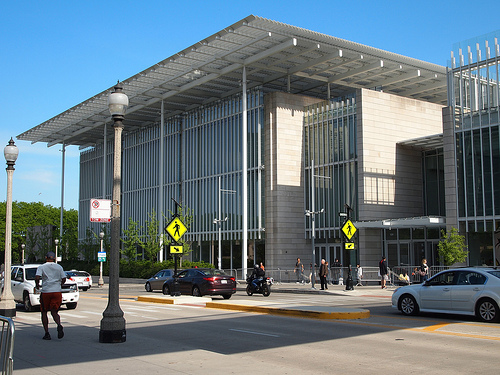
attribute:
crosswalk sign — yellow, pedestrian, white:
[157, 211, 195, 259]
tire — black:
[392, 293, 420, 321]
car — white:
[378, 264, 498, 324]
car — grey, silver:
[141, 264, 187, 297]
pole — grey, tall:
[89, 117, 138, 353]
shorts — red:
[30, 286, 70, 310]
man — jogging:
[34, 248, 75, 342]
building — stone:
[6, 13, 499, 291]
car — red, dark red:
[155, 260, 239, 305]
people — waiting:
[279, 246, 442, 290]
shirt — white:
[31, 261, 78, 299]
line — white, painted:
[119, 302, 315, 356]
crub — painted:
[205, 296, 368, 324]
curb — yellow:
[198, 281, 370, 328]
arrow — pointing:
[345, 239, 357, 253]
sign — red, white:
[83, 193, 114, 227]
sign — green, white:
[90, 245, 115, 262]